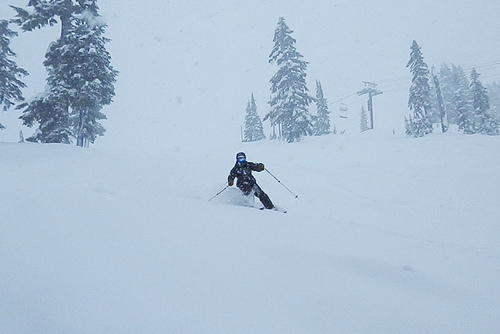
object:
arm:
[248, 162, 259, 171]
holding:
[261, 165, 298, 198]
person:
[227, 152, 276, 210]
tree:
[431, 70, 449, 132]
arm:
[228, 166, 236, 180]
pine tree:
[14, 4, 121, 174]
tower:
[356, 81, 383, 98]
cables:
[326, 85, 364, 106]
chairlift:
[338, 101, 349, 119]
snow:
[285, 57, 300, 68]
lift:
[355, 80, 383, 131]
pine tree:
[358, 102, 372, 133]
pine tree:
[308, 78, 333, 136]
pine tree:
[241, 92, 268, 143]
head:
[235, 152, 246, 162]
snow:
[0, 209, 499, 333]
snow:
[188, 176, 242, 225]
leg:
[253, 182, 274, 209]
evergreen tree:
[263, 14, 319, 143]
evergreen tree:
[17, 0, 123, 148]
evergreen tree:
[399, 35, 442, 136]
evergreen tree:
[467, 67, 500, 136]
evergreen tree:
[0, 18, 29, 130]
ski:
[243, 202, 265, 210]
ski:
[264, 206, 289, 214]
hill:
[0, 130, 499, 334]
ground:
[0, 129, 499, 334]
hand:
[255, 163, 266, 172]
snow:
[408, 34, 498, 139]